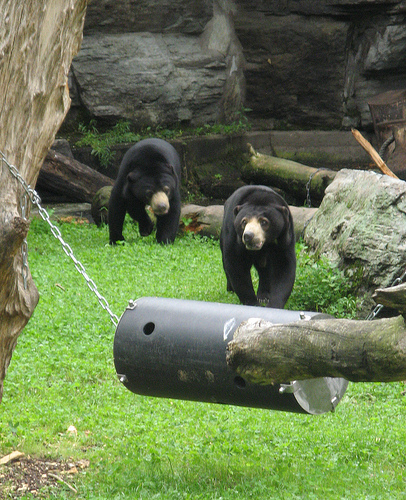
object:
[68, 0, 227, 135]
wall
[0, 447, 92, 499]
dirt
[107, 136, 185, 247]
bear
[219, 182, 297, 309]
bear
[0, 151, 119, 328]
chain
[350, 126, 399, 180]
branch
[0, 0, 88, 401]
tree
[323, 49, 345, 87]
ground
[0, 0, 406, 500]
zoo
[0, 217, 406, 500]
ground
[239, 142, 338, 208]
log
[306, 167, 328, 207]
chain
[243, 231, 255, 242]
nose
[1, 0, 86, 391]
tree trunk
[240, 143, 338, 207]
tree trunk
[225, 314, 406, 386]
tree branch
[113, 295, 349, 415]
barrel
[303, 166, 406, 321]
rock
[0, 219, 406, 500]
grass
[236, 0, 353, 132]
wall